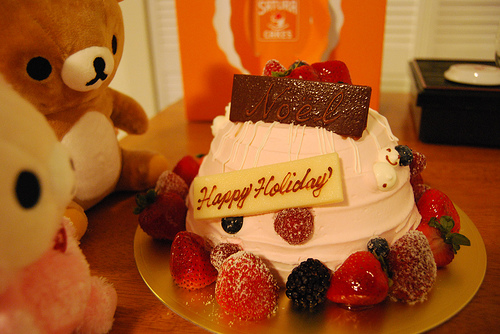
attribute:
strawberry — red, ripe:
[168, 229, 216, 293]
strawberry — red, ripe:
[214, 251, 276, 321]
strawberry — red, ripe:
[325, 251, 392, 304]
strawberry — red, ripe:
[417, 186, 457, 226]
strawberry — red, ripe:
[414, 213, 469, 267]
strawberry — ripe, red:
[420, 189, 462, 244]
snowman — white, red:
[373, 144, 401, 193]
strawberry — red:
[329, 249, 390, 311]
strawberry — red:
[419, 215, 473, 268]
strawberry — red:
[418, 186, 460, 233]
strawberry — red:
[133, 186, 187, 238]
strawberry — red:
[168, 227, 217, 287]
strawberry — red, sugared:
[321, 232, 390, 307]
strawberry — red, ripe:
[418, 210, 462, 267]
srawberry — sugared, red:
[210, 245, 289, 322]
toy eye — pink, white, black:
[10, 164, 49, 209]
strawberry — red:
[215, 252, 273, 317]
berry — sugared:
[328, 248, 388, 309]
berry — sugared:
[282, 255, 334, 316]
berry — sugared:
[213, 247, 283, 324]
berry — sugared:
[170, 229, 216, 289]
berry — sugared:
[137, 189, 187, 242]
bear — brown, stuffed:
[2, 3, 172, 243]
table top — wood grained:
[73, 76, 499, 332]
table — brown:
[439, 124, 492, 218]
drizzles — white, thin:
[312, 126, 335, 148]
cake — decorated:
[126, 54, 472, 326]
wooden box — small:
[404, 52, 498, 151]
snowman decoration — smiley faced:
[374, 145, 401, 188]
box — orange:
[163, 5, 393, 86]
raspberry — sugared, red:
[275, 214, 312, 239]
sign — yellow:
[177, 146, 357, 224]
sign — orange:
[161, 0, 401, 141]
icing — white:
[364, 139, 409, 200]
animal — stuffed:
[3, 76, 118, 329]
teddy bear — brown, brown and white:
[0, 0, 169, 231]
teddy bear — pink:
[0, 79, 125, 327]